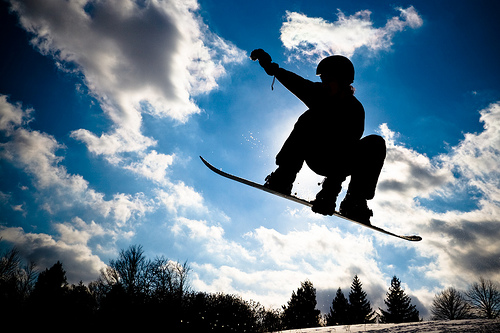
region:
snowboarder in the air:
[167, 28, 437, 263]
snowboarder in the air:
[169, 9, 428, 266]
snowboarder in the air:
[176, 20, 456, 269]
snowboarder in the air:
[155, 30, 426, 267]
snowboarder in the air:
[168, 37, 430, 257]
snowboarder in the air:
[191, 36, 422, 250]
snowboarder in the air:
[185, 40, 459, 259]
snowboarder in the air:
[173, 40, 434, 251]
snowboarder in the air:
[168, 30, 429, 252]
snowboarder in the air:
[165, 10, 427, 260]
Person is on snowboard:
[196, 46, 422, 243]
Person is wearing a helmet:
[197, 46, 422, 242]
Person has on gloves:
[199, 46, 422, 243]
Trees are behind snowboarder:
[0, 245, 498, 330]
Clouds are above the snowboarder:
[5, 3, 498, 301]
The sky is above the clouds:
[1, 0, 497, 311]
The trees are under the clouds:
[0, 250, 495, 330]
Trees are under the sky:
[0, 250, 495, 330]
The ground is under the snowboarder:
[281, 318, 497, 329]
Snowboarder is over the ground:
[196, 46, 423, 243]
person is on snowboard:
[233, 31, 420, 223]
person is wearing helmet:
[310, 49, 367, 85]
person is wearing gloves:
[255, 46, 287, 83]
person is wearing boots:
[232, 149, 382, 223]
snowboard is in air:
[173, 120, 445, 270]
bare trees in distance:
[97, 243, 237, 313]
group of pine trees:
[280, 265, 416, 330]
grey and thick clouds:
[53, 6, 237, 121]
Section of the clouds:
[81, 33, 213, 143]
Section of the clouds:
[73, 164, 197, 272]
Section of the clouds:
[8, 85, 184, 175]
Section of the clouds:
[385, 95, 460, 255]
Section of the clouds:
[437, 153, 479, 258]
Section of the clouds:
[245, 10, 398, 55]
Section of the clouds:
[32, 147, 202, 280]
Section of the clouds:
[85, 120, 212, 211]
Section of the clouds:
[105, 181, 230, 261]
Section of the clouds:
[164, 204, 319, 302]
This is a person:
[229, 33, 453, 290]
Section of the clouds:
[69, 113, 184, 211]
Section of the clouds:
[64, 46, 197, 149]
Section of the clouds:
[224, 228, 328, 281]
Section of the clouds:
[100, 164, 202, 237]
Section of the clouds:
[27, 163, 138, 257]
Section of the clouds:
[390, 125, 467, 221]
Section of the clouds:
[433, 211, 495, 293]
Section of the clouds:
[447, 106, 489, 158]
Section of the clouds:
[270, 2, 390, 52]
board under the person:
[193, 161, 434, 244]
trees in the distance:
[73, 262, 363, 330]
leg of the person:
[324, 126, 408, 222]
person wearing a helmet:
[127, 14, 454, 245]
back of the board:
[386, 208, 434, 253]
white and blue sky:
[83, 30, 250, 177]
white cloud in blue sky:
[173, 213, 243, 265]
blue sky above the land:
[408, 33, 483, 100]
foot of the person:
[226, 141, 323, 213]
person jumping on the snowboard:
[240, 40, 385, 219]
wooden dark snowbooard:
[218, 147, 430, 224]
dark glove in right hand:
[251, 45, 276, 75]